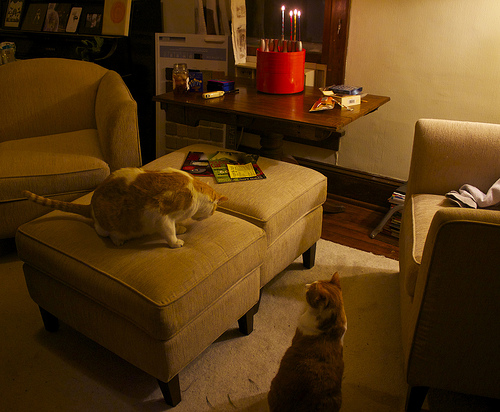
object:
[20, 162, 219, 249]
cat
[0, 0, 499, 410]
living room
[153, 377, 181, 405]
leg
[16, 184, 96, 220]
striped tail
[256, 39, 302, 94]
cup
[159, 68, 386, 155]
table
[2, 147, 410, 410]
floor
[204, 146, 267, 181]
magazine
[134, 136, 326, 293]
chair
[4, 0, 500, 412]
house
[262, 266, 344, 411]
cat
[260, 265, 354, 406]
looking up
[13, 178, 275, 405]
chair